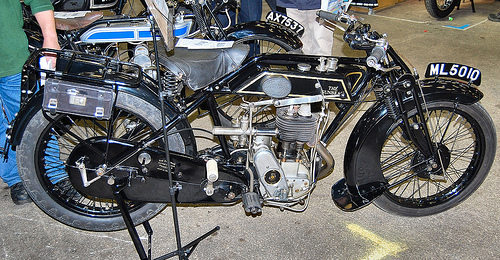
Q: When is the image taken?
A: Not driving.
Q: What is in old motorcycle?
A: Engine.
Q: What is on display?
A: The motorcycle.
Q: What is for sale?
A: The motorcycle.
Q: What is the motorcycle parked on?
A: Concrete.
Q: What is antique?
A: The motorcycle.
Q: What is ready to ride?
A: The motorcycle.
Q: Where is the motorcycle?
A: At a show.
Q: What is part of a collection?
A: The motorcycle.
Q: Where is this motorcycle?
A: In a museum.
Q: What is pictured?
A: Motorcycles.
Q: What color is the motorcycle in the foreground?
A: Black.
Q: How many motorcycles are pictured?
A: Two.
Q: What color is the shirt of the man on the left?
A: Green.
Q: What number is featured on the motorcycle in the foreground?
A: ML5010.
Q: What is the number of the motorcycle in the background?
A: AX7537.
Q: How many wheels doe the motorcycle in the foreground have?
A: Two.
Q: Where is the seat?
A: On the motorcycle.